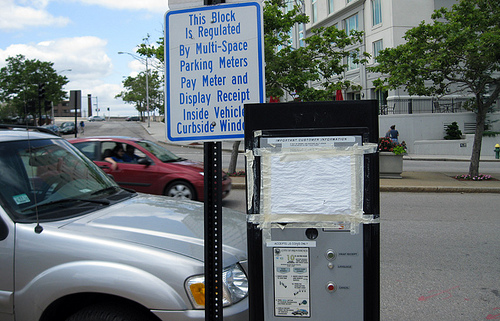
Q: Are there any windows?
A: Yes, there is a window.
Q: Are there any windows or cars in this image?
A: Yes, there is a window.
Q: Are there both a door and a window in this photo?
A: No, there is a window but no doors.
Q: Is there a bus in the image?
A: No, there are no buses.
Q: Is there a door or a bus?
A: No, there are no buses or doors.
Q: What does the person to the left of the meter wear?
A: The person wears a shirt.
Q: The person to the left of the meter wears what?
A: The person wears a shirt.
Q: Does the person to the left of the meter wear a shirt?
A: Yes, the person wears a shirt.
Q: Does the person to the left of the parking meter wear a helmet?
A: No, the person wears a shirt.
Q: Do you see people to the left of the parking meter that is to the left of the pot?
A: Yes, there is a person to the left of the meter.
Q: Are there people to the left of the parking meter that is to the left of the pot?
A: Yes, there is a person to the left of the meter.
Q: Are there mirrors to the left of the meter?
A: No, there is a person to the left of the meter.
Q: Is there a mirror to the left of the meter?
A: No, there is a person to the left of the meter.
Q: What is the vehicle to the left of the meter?
A: The vehicle is a car.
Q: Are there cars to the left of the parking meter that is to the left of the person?
A: Yes, there is a car to the left of the meter.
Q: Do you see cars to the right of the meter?
A: No, the car is to the left of the meter.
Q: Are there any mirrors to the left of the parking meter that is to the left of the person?
A: No, there is a car to the left of the parking meter.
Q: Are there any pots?
A: Yes, there is a pot.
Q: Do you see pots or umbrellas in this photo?
A: Yes, there is a pot.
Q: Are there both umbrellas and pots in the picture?
A: No, there is a pot but no umbrellas.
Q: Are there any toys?
A: No, there are no toys.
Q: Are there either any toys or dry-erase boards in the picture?
A: No, there are no toys or dry-erase boards.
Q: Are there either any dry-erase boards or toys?
A: No, there are no toys or dry-erase boards.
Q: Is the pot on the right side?
A: Yes, the pot is on the right of the image.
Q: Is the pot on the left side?
A: No, the pot is on the right of the image.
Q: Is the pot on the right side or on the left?
A: The pot is on the right of the image.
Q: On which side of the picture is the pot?
A: The pot is on the right of the image.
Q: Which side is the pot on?
A: The pot is on the right of the image.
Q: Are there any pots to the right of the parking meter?
A: Yes, there is a pot to the right of the parking meter.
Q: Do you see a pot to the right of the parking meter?
A: Yes, there is a pot to the right of the parking meter.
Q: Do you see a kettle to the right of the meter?
A: No, there is a pot to the right of the meter.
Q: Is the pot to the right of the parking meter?
A: Yes, the pot is to the right of the parking meter.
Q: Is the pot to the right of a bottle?
A: No, the pot is to the right of the parking meter.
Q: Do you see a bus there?
A: No, there are no buses.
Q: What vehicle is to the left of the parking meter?
A: The vehicle is a car.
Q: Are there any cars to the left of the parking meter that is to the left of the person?
A: Yes, there is a car to the left of the meter.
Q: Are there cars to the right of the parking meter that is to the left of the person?
A: No, the car is to the left of the parking meter.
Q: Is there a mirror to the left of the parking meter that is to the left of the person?
A: No, there is a car to the left of the parking meter.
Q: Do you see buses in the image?
A: No, there are no buses.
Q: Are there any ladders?
A: No, there are no ladders.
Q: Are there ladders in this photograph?
A: No, there are no ladders.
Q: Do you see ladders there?
A: No, there are no ladders.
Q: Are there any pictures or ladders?
A: No, there are no ladders or pictures.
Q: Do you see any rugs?
A: No, there are no rugs.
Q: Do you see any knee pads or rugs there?
A: No, there are no rugs or knee pads.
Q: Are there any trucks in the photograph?
A: No, there are no trucks.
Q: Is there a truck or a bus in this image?
A: No, there are no trucks or buses.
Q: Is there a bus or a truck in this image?
A: No, there are no trucks or buses.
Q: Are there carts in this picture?
A: No, there are no carts.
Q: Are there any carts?
A: No, there are no carts.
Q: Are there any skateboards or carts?
A: No, there are no carts or skateboards.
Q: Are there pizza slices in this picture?
A: No, there are no pizza slices.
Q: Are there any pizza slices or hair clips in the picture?
A: No, there are no pizza slices or hair clips.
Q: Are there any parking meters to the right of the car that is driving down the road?
A: Yes, there is a parking meter to the right of the car.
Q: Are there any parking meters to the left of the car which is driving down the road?
A: No, the parking meter is to the right of the car.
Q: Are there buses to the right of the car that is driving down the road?
A: No, there is a parking meter to the right of the car.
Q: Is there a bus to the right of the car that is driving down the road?
A: No, there is a parking meter to the right of the car.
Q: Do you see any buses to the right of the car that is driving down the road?
A: No, there is a parking meter to the right of the car.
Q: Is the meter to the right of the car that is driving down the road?
A: Yes, the meter is to the right of the car.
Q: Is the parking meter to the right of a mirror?
A: No, the parking meter is to the right of the car.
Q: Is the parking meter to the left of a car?
A: No, the parking meter is to the right of a car.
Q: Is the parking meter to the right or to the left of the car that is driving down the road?
A: The parking meter is to the right of the car.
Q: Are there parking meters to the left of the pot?
A: Yes, there is a parking meter to the left of the pot.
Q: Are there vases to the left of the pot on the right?
A: No, there is a parking meter to the left of the pot.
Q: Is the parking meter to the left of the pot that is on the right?
A: Yes, the parking meter is to the left of the pot.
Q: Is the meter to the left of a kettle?
A: No, the meter is to the left of the pot.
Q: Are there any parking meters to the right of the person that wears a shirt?
A: Yes, there is a parking meter to the right of the person.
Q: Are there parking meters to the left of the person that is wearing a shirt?
A: No, the parking meter is to the right of the person.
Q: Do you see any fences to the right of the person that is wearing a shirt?
A: No, there is a parking meter to the right of the person.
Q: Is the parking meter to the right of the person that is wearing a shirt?
A: Yes, the parking meter is to the right of the person.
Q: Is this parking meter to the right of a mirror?
A: No, the parking meter is to the right of the person.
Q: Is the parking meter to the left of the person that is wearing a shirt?
A: No, the parking meter is to the right of the person.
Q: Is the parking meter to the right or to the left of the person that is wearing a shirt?
A: The parking meter is to the right of the person.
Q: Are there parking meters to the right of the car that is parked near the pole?
A: Yes, there is a parking meter to the right of the car.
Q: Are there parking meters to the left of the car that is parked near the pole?
A: No, the parking meter is to the right of the car.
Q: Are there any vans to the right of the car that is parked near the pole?
A: No, there is a parking meter to the right of the car.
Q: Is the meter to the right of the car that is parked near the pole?
A: Yes, the meter is to the right of the car.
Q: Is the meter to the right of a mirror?
A: No, the meter is to the right of the car.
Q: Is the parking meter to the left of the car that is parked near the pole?
A: No, the parking meter is to the right of the car.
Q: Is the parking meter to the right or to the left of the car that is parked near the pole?
A: The parking meter is to the right of the car.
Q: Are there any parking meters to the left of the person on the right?
A: Yes, there is a parking meter to the left of the person.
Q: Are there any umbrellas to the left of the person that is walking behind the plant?
A: No, there is a parking meter to the left of the person.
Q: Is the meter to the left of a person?
A: Yes, the meter is to the left of a person.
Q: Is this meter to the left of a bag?
A: No, the meter is to the left of a person.